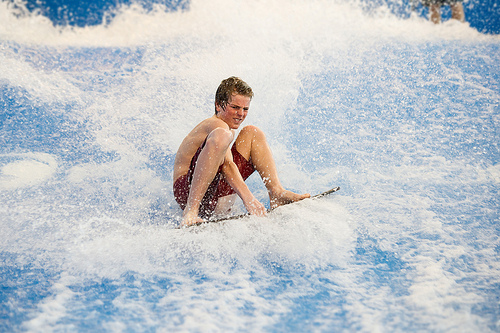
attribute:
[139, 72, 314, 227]
boy —  surfing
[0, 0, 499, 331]
waves — foamy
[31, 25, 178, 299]
ocean — large 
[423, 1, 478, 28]
legs —  surfer's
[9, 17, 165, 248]
water —  in AIR,  SPLASHED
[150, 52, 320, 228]
boy —  crouched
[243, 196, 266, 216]
hand —  boy's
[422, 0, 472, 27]
legs —  in background,  person's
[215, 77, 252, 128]
head —  surfer's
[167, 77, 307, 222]
boy —  blonde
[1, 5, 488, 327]
water —  clear blue, white, blue 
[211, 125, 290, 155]
knees —  bend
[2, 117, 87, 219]
swirl —  foamy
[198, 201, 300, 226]
surfboard — pictured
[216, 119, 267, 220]
arm — the RIGHT,  BOY'S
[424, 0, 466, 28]
object — at RIGHT,  BROWN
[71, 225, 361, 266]
wave —  foamy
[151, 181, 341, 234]
board —  black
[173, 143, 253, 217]
shorts —  red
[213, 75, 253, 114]
hair —  dark brown 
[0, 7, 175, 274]
wave —  ocean's